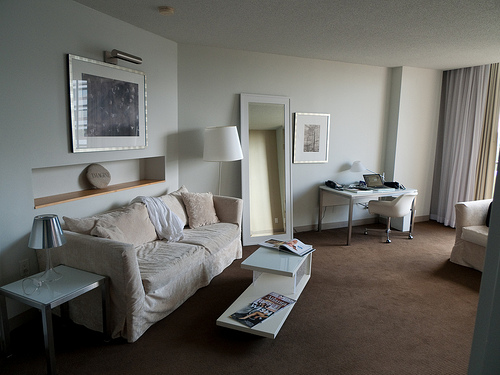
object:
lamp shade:
[347, 158, 367, 174]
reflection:
[254, 123, 280, 228]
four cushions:
[54, 186, 223, 241]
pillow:
[186, 190, 220, 230]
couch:
[447, 196, 493, 273]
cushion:
[462, 224, 488, 249]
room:
[1, 0, 498, 374]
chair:
[367, 188, 419, 244]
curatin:
[436, 61, 484, 231]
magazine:
[226, 288, 297, 328]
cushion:
[63, 202, 158, 243]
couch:
[40, 185, 247, 342]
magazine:
[254, 237, 317, 256]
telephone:
[325, 178, 346, 190]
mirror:
[234, 90, 295, 245]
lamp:
[198, 124, 246, 187]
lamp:
[102, 43, 155, 70]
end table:
[0, 263, 119, 367]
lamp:
[350, 161, 362, 183]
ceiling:
[122, 0, 496, 55]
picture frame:
[66, 50, 156, 154]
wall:
[178, 54, 408, 227]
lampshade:
[201, 122, 243, 162]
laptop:
[362, 170, 389, 190]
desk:
[313, 184, 419, 245]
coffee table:
[215, 239, 315, 341]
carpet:
[384, 336, 440, 363]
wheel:
[385, 237, 392, 244]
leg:
[386, 216, 391, 242]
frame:
[289, 110, 331, 164]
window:
[411, 50, 491, 245]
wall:
[1, 0, 180, 338]